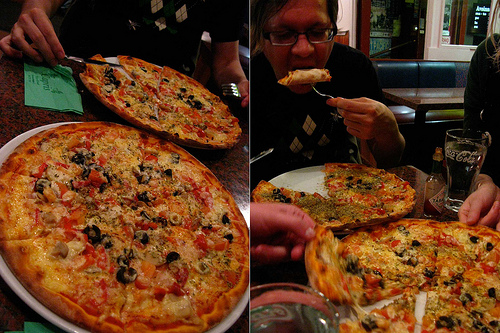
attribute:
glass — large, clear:
[437, 125, 489, 210]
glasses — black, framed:
[257, 24, 337, 46]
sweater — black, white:
[257, 57, 367, 149]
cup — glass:
[403, 109, 499, 225]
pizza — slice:
[0, 107, 255, 320]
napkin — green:
[26, 70, 81, 112]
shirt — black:
[246, 91, 344, 164]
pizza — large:
[11, 121, 247, 322]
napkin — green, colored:
[22, 60, 84, 118]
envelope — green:
[17, 50, 92, 115]